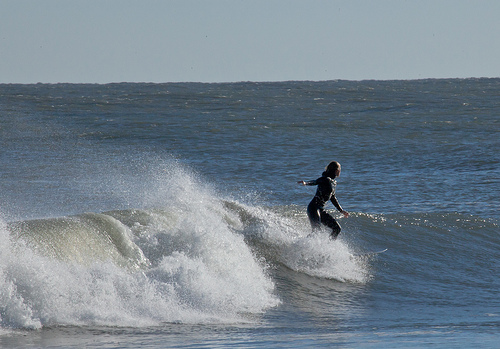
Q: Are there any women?
A: Yes, there is a woman.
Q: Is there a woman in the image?
A: Yes, there is a woman.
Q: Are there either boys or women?
A: Yes, there is a woman.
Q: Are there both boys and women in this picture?
A: No, there is a woman but no boys.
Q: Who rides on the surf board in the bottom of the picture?
A: The woman rides on the surfboard.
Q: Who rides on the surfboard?
A: The woman rides on the surfboard.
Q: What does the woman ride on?
A: The woman rides on the surfboard.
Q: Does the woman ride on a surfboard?
A: Yes, the woman rides on a surfboard.